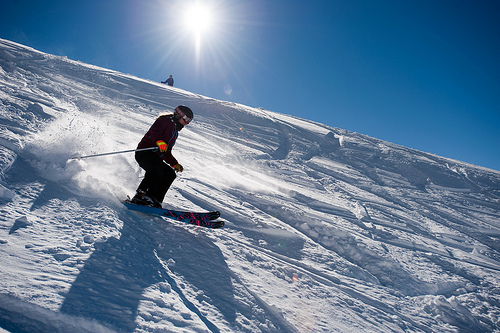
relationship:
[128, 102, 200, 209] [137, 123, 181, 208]
man wearing snowsuit.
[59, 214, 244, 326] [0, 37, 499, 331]
shadow in snow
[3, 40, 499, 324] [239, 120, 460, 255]
hill has tracks.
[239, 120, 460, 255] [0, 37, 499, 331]
tracks in snow.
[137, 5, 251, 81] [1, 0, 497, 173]
sun in sky.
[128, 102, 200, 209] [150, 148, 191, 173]
man wearing gloves.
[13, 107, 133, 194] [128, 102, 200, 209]
cloud behind man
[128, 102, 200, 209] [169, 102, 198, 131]
man wearing helmet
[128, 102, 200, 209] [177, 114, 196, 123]
man wearing goggles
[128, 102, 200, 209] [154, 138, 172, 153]
man wears glove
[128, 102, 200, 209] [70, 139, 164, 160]
man holding pole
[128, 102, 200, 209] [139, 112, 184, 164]
man wearing jacket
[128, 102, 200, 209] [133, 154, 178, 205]
man wearing pants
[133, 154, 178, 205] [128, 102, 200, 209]
pants on man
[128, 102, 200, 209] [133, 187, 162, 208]
man wearing boots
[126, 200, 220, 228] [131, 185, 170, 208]
skis on feet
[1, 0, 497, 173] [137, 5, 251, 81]
sky with sun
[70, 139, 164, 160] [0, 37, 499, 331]
pole in snow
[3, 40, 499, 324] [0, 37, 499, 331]
hill has snow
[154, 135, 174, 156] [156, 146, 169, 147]
glove has stripe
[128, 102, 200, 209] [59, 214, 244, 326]
man cast shadow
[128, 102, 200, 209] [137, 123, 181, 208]
man wearing snowsuit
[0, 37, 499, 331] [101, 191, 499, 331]
snow has tracks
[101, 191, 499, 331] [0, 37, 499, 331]
tracks in snow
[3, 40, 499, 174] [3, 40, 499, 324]
edge on hill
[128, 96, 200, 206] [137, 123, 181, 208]
man wearing clothes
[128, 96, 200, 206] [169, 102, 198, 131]
man wearing helmet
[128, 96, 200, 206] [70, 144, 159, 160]
man holding pole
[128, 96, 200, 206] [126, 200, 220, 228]
man wears skis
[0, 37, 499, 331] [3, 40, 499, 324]
snow on slope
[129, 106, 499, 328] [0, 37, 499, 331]
prints in snow